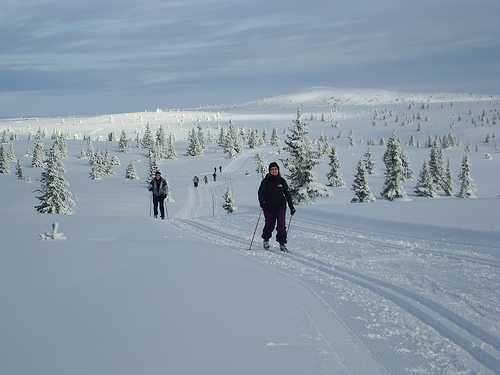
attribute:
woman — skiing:
[258, 161, 296, 252]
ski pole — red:
[249, 200, 266, 252]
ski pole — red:
[285, 208, 294, 233]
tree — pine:
[34, 143, 75, 216]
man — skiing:
[148, 171, 168, 220]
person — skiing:
[192, 175, 199, 189]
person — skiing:
[213, 173, 217, 182]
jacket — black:
[258, 173, 294, 209]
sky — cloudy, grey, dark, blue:
[0, 0, 499, 118]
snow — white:
[1, 87, 499, 373]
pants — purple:
[260, 209, 287, 244]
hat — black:
[269, 163, 280, 171]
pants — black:
[152, 195, 165, 219]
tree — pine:
[456, 153, 478, 198]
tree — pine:
[0, 147, 9, 175]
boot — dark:
[159, 214, 165, 221]